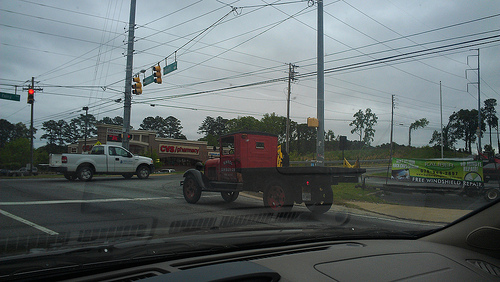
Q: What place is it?
A: It is a road.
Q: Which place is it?
A: It is a road.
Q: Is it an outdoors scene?
A: Yes, it is outdoors.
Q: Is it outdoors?
A: Yes, it is outdoors.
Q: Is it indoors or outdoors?
A: It is outdoors.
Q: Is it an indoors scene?
A: No, it is outdoors.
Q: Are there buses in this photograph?
A: No, there are no buses.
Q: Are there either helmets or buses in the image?
A: No, there are no buses or helmets.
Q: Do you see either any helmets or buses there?
A: No, there are no buses or helmets.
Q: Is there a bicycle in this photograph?
A: No, there are no bicycles.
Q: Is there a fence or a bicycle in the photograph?
A: No, there are no bicycles or fences.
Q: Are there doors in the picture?
A: Yes, there is a door.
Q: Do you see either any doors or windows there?
A: Yes, there is a door.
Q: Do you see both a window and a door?
A: Yes, there are both a door and a window.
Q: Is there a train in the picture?
A: No, there are no trains.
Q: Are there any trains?
A: No, there are no trains.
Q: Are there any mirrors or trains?
A: No, there are no trains or mirrors.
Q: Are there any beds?
A: Yes, there is a bed.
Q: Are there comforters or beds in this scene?
A: Yes, there is a bed.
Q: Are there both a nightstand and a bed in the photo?
A: No, there is a bed but no nightstands.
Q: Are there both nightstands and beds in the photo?
A: No, there is a bed but no nightstands.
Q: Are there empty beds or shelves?
A: Yes, there is an empty bed.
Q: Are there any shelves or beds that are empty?
A: Yes, the bed is empty.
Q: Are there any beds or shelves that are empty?
A: Yes, the bed is empty.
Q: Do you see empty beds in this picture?
A: Yes, there is an empty bed.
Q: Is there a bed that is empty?
A: Yes, there is a bed that is empty.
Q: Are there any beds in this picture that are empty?
A: Yes, there is a bed that is empty.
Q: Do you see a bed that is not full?
A: Yes, there is a empty bed.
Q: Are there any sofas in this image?
A: No, there are no sofas.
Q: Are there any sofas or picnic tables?
A: No, there are no sofas or picnic tables.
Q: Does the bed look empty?
A: Yes, the bed is empty.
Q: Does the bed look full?
A: No, the bed is empty.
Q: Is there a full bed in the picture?
A: No, there is a bed but it is empty.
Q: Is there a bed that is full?
A: No, there is a bed but it is empty.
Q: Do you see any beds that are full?
A: No, there is a bed but it is empty.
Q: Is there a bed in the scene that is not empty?
A: No, there is a bed but it is empty.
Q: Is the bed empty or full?
A: The bed is empty.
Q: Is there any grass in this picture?
A: Yes, there is grass.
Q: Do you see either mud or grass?
A: Yes, there is grass.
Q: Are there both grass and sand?
A: No, there is grass but no sand.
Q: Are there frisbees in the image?
A: No, there are no frisbees.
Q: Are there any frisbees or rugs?
A: No, there are no frisbees or rugs.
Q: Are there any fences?
A: No, there are no fences.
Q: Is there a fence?
A: No, there are no fences.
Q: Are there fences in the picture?
A: No, there are no fences.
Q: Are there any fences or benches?
A: No, there are no fences or benches.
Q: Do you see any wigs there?
A: No, there are no wigs.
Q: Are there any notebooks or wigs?
A: No, there are no wigs or notebooks.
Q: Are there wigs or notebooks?
A: No, there are no wigs or notebooks.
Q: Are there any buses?
A: No, there are no buses.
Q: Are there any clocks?
A: No, there are no clocks.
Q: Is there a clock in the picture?
A: No, there are no clocks.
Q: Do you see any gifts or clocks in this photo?
A: No, there are no clocks or gifts.